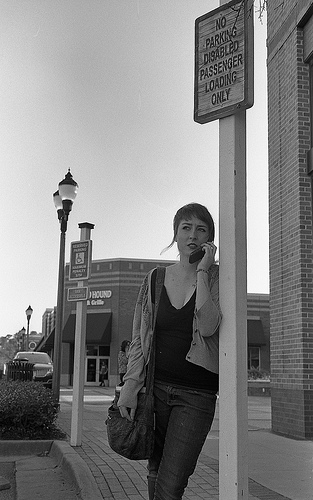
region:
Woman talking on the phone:
[119, 202, 225, 499]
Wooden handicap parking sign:
[65, 233, 96, 305]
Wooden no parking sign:
[179, 0, 267, 123]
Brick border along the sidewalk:
[88, 455, 125, 494]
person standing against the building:
[90, 357, 113, 387]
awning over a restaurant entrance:
[84, 302, 114, 344]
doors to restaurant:
[84, 348, 101, 389]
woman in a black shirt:
[134, 201, 246, 388]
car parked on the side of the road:
[14, 347, 53, 387]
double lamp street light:
[39, 161, 78, 395]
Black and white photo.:
[3, 13, 266, 495]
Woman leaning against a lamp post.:
[99, 185, 234, 493]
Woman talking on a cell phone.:
[100, 194, 227, 495]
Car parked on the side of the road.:
[10, 343, 62, 391]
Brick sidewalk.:
[55, 398, 236, 499]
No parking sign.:
[184, 6, 263, 128]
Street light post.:
[45, 163, 77, 427]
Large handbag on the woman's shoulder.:
[101, 263, 169, 474]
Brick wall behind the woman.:
[265, 58, 310, 440]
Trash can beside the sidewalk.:
[2, 355, 39, 387]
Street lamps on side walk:
[40, 174, 94, 221]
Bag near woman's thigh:
[97, 372, 157, 450]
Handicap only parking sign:
[65, 242, 96, 287]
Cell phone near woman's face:
[184, 247, 213, 265]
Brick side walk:
[92, 454, 123, 496]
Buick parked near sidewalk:
[15, 331, 51, 382]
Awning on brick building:
[66, 306, 122, 344]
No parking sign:
[186, 4, 251, 113]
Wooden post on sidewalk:
[217, 334, 259, 498]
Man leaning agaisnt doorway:
[95, 355, 107, 393]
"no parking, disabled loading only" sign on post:
[193, 0, 251, 120]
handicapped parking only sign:
[66, 235, 90, 279]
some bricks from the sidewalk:
[105, 462, 133, 488]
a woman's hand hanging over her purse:
[102, 384, 162, 457]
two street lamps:
[47, 163, 83, 237]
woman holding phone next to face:
[156, 197, 227, 281]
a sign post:
[218, 112, 245, 499]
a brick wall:
[270, 8, 312, 437]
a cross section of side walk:
[251, 438, 310, 485]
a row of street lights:
[3, 300, 41, 353]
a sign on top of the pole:
[193, 5, 259, 127]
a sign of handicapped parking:
[64, 236, 93, 306]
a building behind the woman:
[60, 260, 303, 395]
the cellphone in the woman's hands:
[190, 246, 206, 264]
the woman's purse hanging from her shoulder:
[103, 335, 152, 461]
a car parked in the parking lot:
[13, 349, 50, 387]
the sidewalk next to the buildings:
[64, 376, 298, 498]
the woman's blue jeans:
[150, 376, 198, 497]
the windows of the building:
[247, 345, 259, 373]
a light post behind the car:
[22, 305, 38, 352]